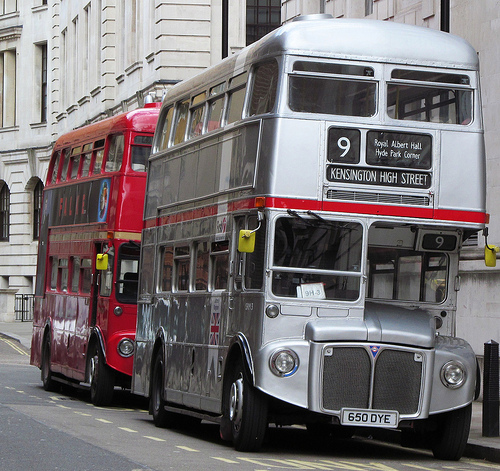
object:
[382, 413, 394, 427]
letter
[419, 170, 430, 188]
letter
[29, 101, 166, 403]
bus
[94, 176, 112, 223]
orange diamond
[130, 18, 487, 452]
bus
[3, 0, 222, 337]
building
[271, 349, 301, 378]
headlamps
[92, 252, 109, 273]
mirror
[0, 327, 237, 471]
street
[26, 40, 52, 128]
windows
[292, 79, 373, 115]
seats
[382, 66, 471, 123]
window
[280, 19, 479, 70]
2nd level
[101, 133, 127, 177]
window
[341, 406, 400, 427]
tag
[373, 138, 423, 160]
word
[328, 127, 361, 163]
banner